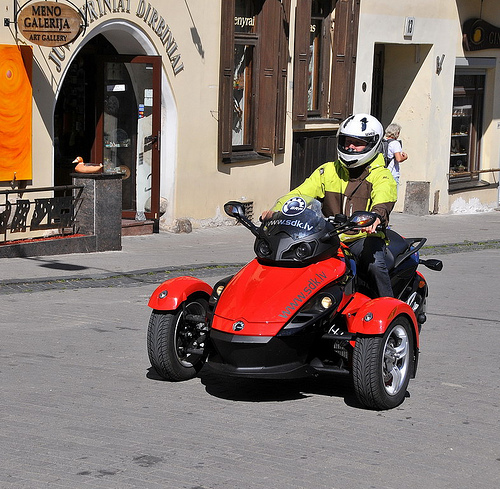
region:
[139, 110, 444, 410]
Man on a motorcycle.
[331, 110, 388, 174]
white helmet on the head.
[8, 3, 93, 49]
Sign on the building.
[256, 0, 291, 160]
Brown shutter on the window.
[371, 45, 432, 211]
Door in the window.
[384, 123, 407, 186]
Person walking on the street.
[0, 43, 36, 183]
Orange sign on the building.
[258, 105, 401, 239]
Brown and yellow jacket on man.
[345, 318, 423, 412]
Black tire on the motorcycle.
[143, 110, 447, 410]
the man on the trike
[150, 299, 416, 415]
the front wheels of the trike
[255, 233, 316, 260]
the front lights on the trike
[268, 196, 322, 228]
the widnshield on the fron tof the trike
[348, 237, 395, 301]
the leg of the jean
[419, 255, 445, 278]
the brake light on the trike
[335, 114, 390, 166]
the white helmet on the mans head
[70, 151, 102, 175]
the duck outside the gallery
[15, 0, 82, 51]
the round sign for the Art Gallery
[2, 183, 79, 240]
the hand rail outside trhe building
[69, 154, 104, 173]
an orange duck statue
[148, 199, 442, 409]
a three wheel motorcycle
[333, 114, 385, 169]
a white motorcycle helmet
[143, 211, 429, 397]
a red and black motorcycle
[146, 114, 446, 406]
a guy riding a red three wheel motorcycle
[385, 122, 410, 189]
a person walking on the sidewalk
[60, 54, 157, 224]
glass doors to front of building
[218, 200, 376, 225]
a set of mirrors on a motorcycle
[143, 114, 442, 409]
A person riding a tricycle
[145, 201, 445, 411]
A red and black motorized tricycle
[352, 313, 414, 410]
A front tire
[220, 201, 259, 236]
A rear view mirror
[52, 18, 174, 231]
An arched door way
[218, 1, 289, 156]
A window with wooden shutters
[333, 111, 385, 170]
A white helmet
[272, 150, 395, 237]
A winter coat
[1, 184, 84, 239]
A metal railing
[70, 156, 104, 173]
A fake duck sitting on a pillar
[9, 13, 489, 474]
Photo taken during the day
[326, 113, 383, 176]
Helmet on the man's head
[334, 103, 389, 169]
The helmet is white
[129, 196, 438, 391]
The motorcycle is red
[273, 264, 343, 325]
www.sdk.lv written on the bike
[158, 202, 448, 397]
Three wheeled motorcycle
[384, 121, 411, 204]
Person walking on the sidewalk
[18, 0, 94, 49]
Meno Galerija Art Gallery sign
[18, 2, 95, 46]
The sign is made of wood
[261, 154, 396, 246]
The man's coat is green and brown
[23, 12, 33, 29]
black letter on sign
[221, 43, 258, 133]
a window on the building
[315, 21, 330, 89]
a window on the building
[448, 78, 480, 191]
a window on the building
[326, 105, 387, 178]
a helmet on the man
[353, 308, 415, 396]
a tire on the motorcycle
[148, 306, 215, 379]
a tire on the motorcycle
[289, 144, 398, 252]
a jacket on the person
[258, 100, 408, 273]
man sitting on motorcycle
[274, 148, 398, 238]
green and black jacket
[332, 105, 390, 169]
white round motorcycle helmet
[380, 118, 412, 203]
woman wearing white shirt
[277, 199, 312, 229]
black and white circle on front of motorcycle